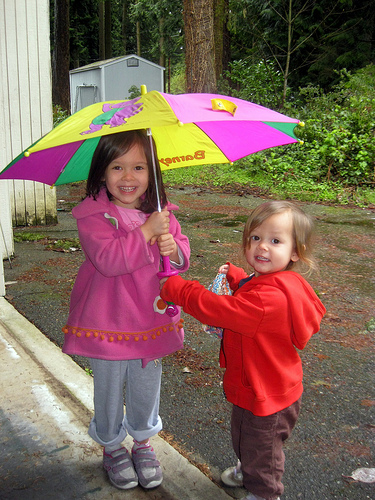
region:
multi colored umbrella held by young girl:
[2, 85, 307, 175]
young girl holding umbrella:
[62, 127, 191, 488]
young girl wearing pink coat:
[57, 128, 193, 490]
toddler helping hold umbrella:
[159, 200, 325, 499]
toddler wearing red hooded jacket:
[161, 200, 329, 498]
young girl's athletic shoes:
[100, 440, 163, 489]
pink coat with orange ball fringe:
[63, 188, 191, 368]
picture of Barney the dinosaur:
[79, 98, 147, 134]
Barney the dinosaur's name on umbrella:
[158, 149, 207, 166]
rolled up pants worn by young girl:
[90, 354, 163, 446]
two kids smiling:
[69, 129, 302, 497]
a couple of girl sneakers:
[98, 442, 163, 489]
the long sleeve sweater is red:
[161, 263, 325, 416]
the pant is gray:
[68, 357, 166, 441]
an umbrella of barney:
[0, 84, 304, 189]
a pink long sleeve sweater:
[64, 185, 188, 370]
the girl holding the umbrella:
[0, 88, 304, 271]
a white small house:
[68, 56, 165, 98]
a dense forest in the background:
[54, 4, 367, 55]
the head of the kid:
[235, 202, 314, 273]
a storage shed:
[59, 50, 168, 112]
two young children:
[56, 125, 316, 380]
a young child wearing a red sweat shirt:
[218, 220, 326, 402]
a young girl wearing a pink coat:
[48, 181, 174, 365]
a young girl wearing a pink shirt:
[113, 207, 152, 234]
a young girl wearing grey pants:
[90, 332, 174, 453]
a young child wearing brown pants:
[207, 384, 303, 476]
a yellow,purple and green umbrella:
[0, 91, 283, 209]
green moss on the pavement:
[333, 202, 368, 279]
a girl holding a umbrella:
[96, 121, 194, 259]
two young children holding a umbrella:
[54, 101, 328, 312]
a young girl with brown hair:
[77, 117, 187, 238]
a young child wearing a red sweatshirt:
[204, 244, 317, 407]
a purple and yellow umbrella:
[32, 81, 257, 159]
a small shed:
[59, 50, 169, 114]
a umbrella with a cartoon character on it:
[70, 77, 149, 152]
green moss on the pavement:
[203, 207, 250, 232]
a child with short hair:
[226, 197, 317, 280]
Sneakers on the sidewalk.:
[93, 436, 164, 491]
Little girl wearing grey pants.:
[81, 355, 162, 447]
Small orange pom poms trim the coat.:
[55, 317, 185, 346]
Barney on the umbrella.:
[8, 84, 303, 190]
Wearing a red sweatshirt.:
[156, 267, 335, 412]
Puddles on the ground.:
[312, 211, 368, 230]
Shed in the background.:
[67, 63, 172, 101]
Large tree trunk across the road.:
[179, 3, 213, 88]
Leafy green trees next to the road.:
[304, 74, 365, 196]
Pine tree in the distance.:
[291, 12, 366, 91]